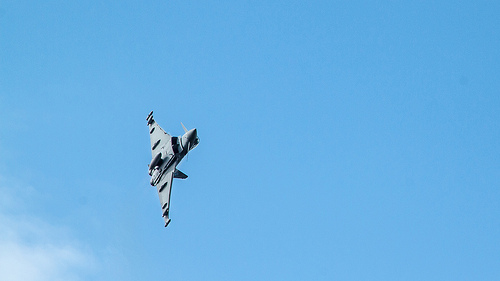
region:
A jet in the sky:
[143, 108, 201, 230]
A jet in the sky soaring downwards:
[143, 107, 200, 230]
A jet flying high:
[143, 109, 200, 230]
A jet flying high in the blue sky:
[143, 109, 200, 229]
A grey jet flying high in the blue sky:
[143, 108, 201, 232]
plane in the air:
[108, 89, 247, 239]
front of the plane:
[174, 103, 224, 169]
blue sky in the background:
[253, 42, 371, 159]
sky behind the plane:
[217, 62, 337, 163]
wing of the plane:
[122, 97, 186, 152]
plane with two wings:
[106, 84, 218, 234]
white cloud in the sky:
[5, 206, 98, 278]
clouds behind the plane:
[21, 179, 133, 279]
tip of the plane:
[178, 115, 218, 160]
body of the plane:
[141, 134, 186, 181]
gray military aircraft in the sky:
[140, 111, 205, 228]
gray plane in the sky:
[141, 109, 201, 234]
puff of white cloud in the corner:
[4, 191, 105, 278]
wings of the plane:
[142, 109, 173, 224]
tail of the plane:
[173, 168, 190, 182]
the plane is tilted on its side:
[140, 99, 209, 224]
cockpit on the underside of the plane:
[187, 133, 200, 150]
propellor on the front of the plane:
[179, 119, 201, 149]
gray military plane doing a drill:
[136, 96, 201, 235]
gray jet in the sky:
[134, 105, 206, 230]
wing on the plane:
[119, 100, 173, 151]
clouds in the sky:
[8, 194, 105, 279]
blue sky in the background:
[290, 69, 422, 178]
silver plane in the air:
[96, 82, 228, 275]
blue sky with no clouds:
[305, 39, 430, 140]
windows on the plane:
[163, 126, 190, 167]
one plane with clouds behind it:
[121, 92, 226, 234]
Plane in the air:
[141, 102, 199, 227]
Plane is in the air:
[136, 105, 201, 232]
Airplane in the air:
[141, 97, 204, 228]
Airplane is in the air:
[136, 104, 208, 231]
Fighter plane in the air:
[133, 106, 210, 231]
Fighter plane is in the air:
[141, 106, 201, 231]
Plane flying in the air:
[138, 103, 201, 229]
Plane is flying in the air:
[139, 101, 205, 232]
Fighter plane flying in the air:
[139, 107, 205, 236]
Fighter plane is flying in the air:
[142, 105, 208, 229]